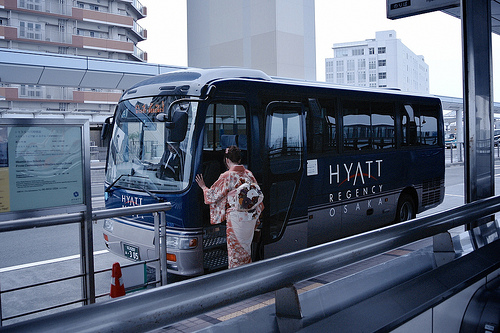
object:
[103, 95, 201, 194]
windshield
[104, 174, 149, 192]
windshield wiper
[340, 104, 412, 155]
window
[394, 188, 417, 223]
tire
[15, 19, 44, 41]
window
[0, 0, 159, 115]
building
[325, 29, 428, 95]
building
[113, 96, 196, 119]
bus info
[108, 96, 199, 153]
mirrors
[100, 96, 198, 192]
window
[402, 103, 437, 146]
window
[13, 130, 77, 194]
information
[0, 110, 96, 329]
stand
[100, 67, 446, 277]
shuttle bus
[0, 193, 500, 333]
guard rail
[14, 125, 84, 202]
signs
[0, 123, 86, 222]
glass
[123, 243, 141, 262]
license plate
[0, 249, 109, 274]
line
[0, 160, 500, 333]
road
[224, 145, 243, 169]
hair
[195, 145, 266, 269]
lady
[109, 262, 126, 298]
cone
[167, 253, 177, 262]
light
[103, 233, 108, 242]
light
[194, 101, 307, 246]
bus door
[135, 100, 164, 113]
digital sign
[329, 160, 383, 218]
hotel logo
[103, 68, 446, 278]
van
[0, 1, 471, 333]
dividing wall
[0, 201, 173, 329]
metal handrail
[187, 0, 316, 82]
multi-storied building